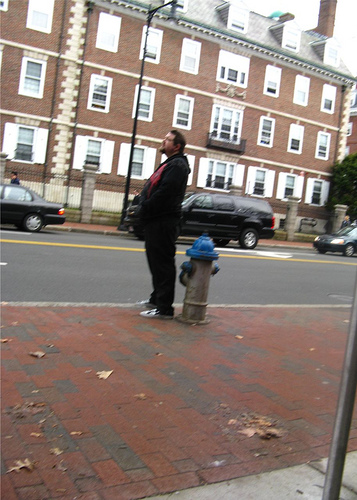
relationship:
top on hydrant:
[193, 234, 214, 259] [189, 231, 212, 324]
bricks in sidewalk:
[95, 388, 133, 414] [85, 369, 169, 431]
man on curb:
[152, 127, 178, 322] [126, 300, 137, 314]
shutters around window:
[5, 119, 52, 167] [19, 125, 35, 163]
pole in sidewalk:
[327, 427, 345, 496] [294, 467, 323, 500]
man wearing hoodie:
[152, 127, 178, 322] [158, 158, 183, 233]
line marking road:
[54, 241, 138, 253] [64, 250, 122, 270]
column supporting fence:
[84, 158, 98, 216] [102, 176, 120, 218]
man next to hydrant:
[152, 127, 178, 322] [189, 231, 212, 324]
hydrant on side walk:
[189, 231, 212, 324] [143, 303, 357, 499]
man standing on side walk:
[152, 127, 178, 322] [143, 303, 357, 499]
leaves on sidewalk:
[246, 417, 278, 441] [85, 369, 169, 431]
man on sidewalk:
[152, 127, 178, 322] [85, 369, 169, 431]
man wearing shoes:
[152, 127, 178, 322] [141, 306, 178, 320]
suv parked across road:
[189, 188, 275, 233] [0, 225, 357, 305]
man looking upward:
[152, 127, 178, 322] [160, 132, 184, 156]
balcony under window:
[210, 132, 246, 156] [211, 104, 243, 131]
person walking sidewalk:
[10, 169, 20, 184] [80, 218, 102, 229]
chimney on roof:
[315, 3, 336, 33] [310, 37, 325, 60]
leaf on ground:
[95, 367, 113, 382] [115, 377, 133, 391]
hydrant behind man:
[189, 231, 212, 324] [152, 127, 178, 322]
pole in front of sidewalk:
[327, 427, 345, 496] [85, 369, 169, 431]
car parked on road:
[6, 183, 69, 230] [64, 250, 122, 270]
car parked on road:
[189, 188, 275, 233] [64, 250, 122, 270]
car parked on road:
[325, 222, 357, 251] [64, 250, 122, 270]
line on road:
[54, 241, 138, 253] [64, 250, 122, 270]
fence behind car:
[102, 176, 120, 218] [6, 183, 69, 230]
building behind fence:
[44, 9, 356, 128] [102, 176, 120, 218]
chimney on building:
[315, 3, 336, 33] [44, 9, 356, 128]